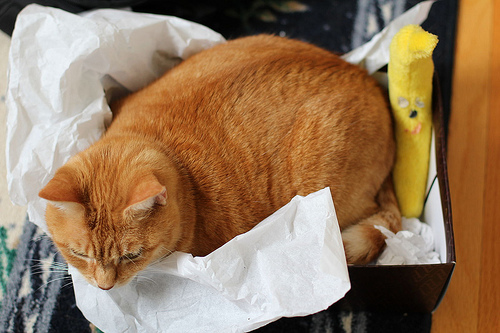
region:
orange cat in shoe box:
[37, 23, 389, 286]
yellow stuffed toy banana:
[390, 20, 441, 216]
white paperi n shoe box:
[7, 8, 349, 329]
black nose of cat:
[95, 280, 117, 292]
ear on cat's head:
[116, 168, 172, 213]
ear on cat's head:
[35, 172, 85, 214]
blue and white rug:
[1, 238, 61, 328]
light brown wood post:
[435, 2, 499, 331]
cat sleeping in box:
[48, 25, 397, 290]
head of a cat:
[25, 107, 215, 304]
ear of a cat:
[96, 154, 190, 239]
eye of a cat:
[54, 241, 102, 285]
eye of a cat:
[112, 227, 172, 266]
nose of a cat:
[85, 270, 135, 304]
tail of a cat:
[340, 202, 447, 269]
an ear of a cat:
[14, 173, 88, 227]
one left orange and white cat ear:
[122, 172, 169, 222]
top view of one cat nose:
[93, 261, 117, 293]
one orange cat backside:
[223, 25, 389, 137]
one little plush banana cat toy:
[383, 22, 437, 219]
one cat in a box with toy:
[37, 32, 457, 319]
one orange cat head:
[37, 142, 187, 292]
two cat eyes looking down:
[65, 247, 150, 269]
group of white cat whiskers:
[23, 254, 73, 293]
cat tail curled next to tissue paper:
[337, 197, 407, 281]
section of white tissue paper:
[178, 185, 358, 332]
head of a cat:
[25, 125, 188, 310]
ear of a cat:
[120, 161, 191, 221]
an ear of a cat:
[25, 143, 93, 228]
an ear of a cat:
[113, 165, 195, 240]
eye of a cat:
[69, 239, 100, 257]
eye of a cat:
[112, 223, 170, 267]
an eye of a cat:
[60, 239, 102, 263]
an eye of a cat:
[125, 249, 153, 269]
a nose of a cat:
[96, 273, 140, 293]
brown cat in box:
[37, 37, 378, 294]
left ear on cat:
[126, 174, 169, 220]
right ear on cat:
[32, 185, 89, 230]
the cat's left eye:
[118, 254, 141, 264]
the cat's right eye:
[66, 239, 87, 269]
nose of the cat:
[91, 261, 117, 292]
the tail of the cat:
[344, 194, 395, 260]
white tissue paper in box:
[152, 256, 323, 329]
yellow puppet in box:
[392, 37, 431, 216]